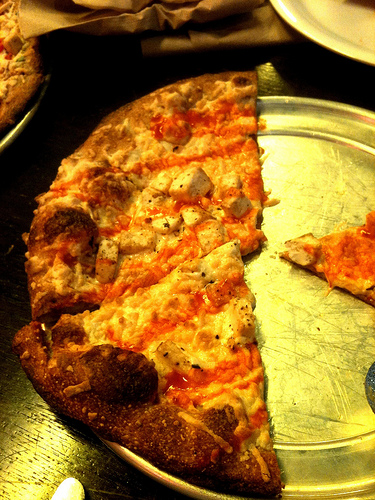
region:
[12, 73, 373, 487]
partially eaten chicken pizza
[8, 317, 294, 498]
crispy brown pizza crust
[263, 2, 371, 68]
edge of a shiny silver pizza pan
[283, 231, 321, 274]
piece of white meat chicken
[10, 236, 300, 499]
single piece of chicken pizza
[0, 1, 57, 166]
edge of another nearby pizza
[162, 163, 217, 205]
piece of white meat chicken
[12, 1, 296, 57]
wrinkled brown paper bag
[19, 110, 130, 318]
crispy edge of pizza crust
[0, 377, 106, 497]
reflection of over head light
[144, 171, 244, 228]
diced chicken on top of pizza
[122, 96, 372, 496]
scarred metal pizza serving tray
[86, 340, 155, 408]
air bubble in crust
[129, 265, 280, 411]
cheese and buffalo wing sauce on top of pizza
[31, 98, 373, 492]
pizza with two slices missing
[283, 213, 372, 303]
pizza slice thats tip is the only thing you can see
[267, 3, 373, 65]
edge of round metal serving tray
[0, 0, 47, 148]
trey with another pizza on it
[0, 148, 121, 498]
wooden table with lot of wear and tear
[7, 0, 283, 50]
crumpled brown napkin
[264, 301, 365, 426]
Scratches on the baking pan.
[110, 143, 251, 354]
Pizza on the baking pan.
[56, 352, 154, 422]
The crust of the pizza is burnt.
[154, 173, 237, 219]
Chunk of chicken on the pizza.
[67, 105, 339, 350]
Some of the slices are missing.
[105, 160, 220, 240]
Cheese on the pizza.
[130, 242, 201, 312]
Red tomatoe sauce on the pizza.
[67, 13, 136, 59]
A brown napkin on the table.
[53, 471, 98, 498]
Part of the knife on the table.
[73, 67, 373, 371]
The pizza is on top of a baking pan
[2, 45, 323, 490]
pizza on a table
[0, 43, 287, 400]
slices of pizza on table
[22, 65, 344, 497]
slices of pizza on trey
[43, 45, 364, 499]
pizza cut up on a trey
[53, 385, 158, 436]
black burnt crust of pizza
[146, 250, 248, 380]
white cheese on top of pizza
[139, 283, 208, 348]
red sauce beneath cheese of pizza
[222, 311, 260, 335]
white chicken on top of pizza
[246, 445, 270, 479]
hardened piece of cheese on crust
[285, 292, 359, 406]
silver scratched up pizza trey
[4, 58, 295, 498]
half eaten pizza cut in slices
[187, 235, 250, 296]
piece of chicken on a slice of pizza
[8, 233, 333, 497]
slice of handtossed pizza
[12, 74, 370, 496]
half eaten pizza on a silver platter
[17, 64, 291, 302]
slice of chicken and cheese pizza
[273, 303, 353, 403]
scratch marks on silver pizza plate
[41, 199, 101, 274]
burned spot on a slice of pizza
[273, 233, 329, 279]
corner of a slice of pizza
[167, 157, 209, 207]
large piece of chicken on a pizza